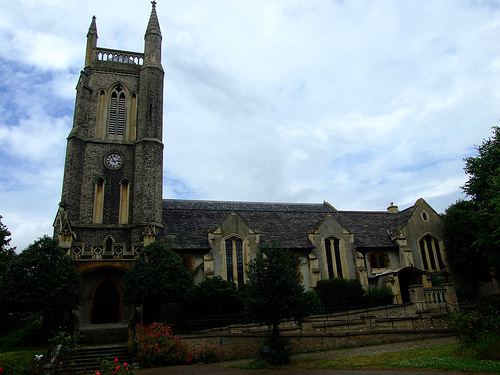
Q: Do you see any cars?
A: No, there are no cars.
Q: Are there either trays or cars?
A: No, there are no cars or trays.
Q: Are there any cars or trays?
A: No, there are no cars or trays.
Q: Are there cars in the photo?
A: No, there are no cars.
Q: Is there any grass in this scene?
A: Yes, there is grass.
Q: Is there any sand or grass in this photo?
A: Yes, there is grass.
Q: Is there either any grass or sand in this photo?
A: Yes, there is grass.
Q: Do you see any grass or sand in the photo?
A: Yes, there is grass.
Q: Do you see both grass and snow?
A: No, there is grass but no snow.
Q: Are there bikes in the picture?
A: No, there are no bikes.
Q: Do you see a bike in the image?
A: No, there are no bikes.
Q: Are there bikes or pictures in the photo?
A: No, there are no bikes or pictures.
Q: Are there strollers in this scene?
A: No, there are no strollers.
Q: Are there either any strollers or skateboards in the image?
A: No, there are no strollers or skateboards.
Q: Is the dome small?
A: Yes, the dome is small.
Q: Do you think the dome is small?
A: Yes, the dome is small.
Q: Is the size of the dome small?
A: Yes, the dome is small.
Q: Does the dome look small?
A: Yes, the dome is small.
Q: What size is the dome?
A: The dome is small.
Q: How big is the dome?
A: The dome is small.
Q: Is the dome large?
A: No, the dome is small.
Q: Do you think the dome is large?
A: No, the dome is small.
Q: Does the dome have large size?
A: No, the dome is small.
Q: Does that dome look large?
A: No, the dome is small.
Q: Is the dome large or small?
A: The dome is small.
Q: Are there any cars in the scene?
A: No, there are no cars.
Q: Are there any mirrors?
A: No, there are no mirrors.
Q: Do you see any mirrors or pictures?
A: No, there are no mirrors or pictures.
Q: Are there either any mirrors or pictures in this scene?
A: No, there are no mirrors or pictures.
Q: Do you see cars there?
A: No, there are no cars.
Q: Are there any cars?
A: No, there are no cars.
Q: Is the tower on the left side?
A: Yes, the tower is on the left of the image.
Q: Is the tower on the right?
A: No, the tower is on the left of the image.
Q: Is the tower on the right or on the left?
A: The tower is on the left of the image.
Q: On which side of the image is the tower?
A: The tower is on the left of the image.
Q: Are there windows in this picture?
A: Yes, there is a window.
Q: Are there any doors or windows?
A: Yes, there is a window.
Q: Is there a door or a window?
A: Yes, there is a window.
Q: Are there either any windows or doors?
A: Yes, there is a window.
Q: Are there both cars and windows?
A: No, there is a window but no cars.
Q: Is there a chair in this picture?
A: No, there are no chairs.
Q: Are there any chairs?
A: No, there are no chairs.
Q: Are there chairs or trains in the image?
A: No, there are no chairs or trains.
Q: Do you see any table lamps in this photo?
A: No, there are no table lamps.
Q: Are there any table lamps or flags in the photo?
A: No, there are no table lamps or flags.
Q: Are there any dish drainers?
A: No, there are no dish drainers.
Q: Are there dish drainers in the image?
A: No, there are no dish drainers.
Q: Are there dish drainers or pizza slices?
A: No, there are no dish drainers or pizza slices.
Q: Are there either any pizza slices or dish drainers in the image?
A: No, there are no dish drainers or pizza slices.